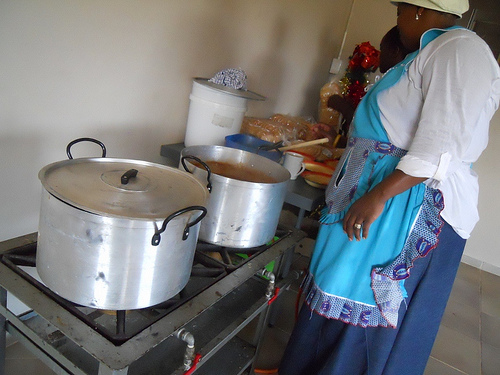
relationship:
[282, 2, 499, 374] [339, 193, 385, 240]
person has hand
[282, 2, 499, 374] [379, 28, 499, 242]
person wearing shirt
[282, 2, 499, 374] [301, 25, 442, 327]
person wearing apron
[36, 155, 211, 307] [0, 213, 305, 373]
pot atop stove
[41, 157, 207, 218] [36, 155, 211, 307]
lid atop pot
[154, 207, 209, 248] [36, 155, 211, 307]
handle on pot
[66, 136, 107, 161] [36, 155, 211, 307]
handle on pot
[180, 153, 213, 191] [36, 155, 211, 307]
handle on pot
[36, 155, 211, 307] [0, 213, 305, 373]
pot on stove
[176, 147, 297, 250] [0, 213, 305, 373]
pot atop stove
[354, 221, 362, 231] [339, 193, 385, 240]
ring on hand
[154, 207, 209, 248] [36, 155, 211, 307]
handle attached to pot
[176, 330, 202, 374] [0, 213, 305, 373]
line attached to stove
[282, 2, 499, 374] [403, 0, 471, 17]
person wearing hat